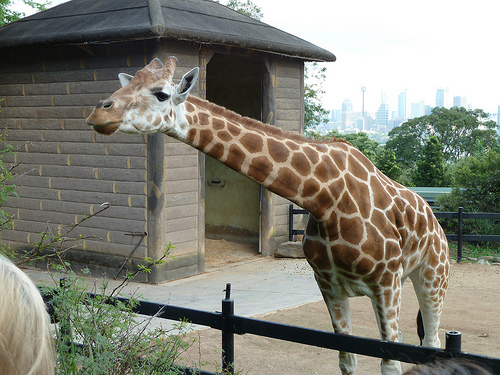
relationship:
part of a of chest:
[307, 229, 358, 260] [299, 180, 362, 285]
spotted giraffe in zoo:
[218, 129, 340, 188] [2, 4, 498, 373]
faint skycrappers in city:
[335, 78, 488, 149] [306, 82, 498, 156]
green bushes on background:
[383, 111, 499, 245] [312, 104, 497, 165]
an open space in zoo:
[330, 106, 497, 177] [2, 4, 498, 373]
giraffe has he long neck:
[73, 44, 454, 373] [181, 94, 318, 221]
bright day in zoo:
[43, 9, 448, 300] [2, 4, 498, 373]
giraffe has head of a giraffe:
[73, 44, 454, 373] [73, 60, 202, 149]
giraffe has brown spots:
[73, 44, 454, 373] [288, 138, 338, 187]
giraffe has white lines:
[73, 44, 454, 373] [229, 137, 260, 168]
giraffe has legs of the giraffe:
[73, 44, 454, 373] [326, 290, 448, 371]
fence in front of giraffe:
[54, 279, 399, 371] [73, 44, 454, 373]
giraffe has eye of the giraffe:
[73, 44, 454, 373] [154, 90, 177, 114]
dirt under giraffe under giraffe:
[295, 310, 479, 374] [73, 44, 454, 373]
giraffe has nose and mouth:
[73, 44, 454, 373] [82, 89, 119, 144]